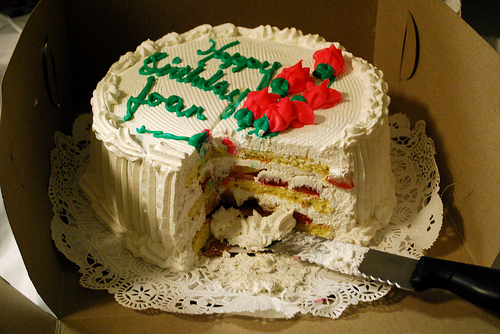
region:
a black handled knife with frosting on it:
[184, 184, 499, 319]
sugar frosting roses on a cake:
[227, 34, 357, 149]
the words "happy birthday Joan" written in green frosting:
[115, 28, 301, 168]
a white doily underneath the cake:
[27, 54, 456, 330]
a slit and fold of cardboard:
[387, 7, 435, 90]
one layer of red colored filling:
[188, 161, 360, 206]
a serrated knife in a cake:
[195, 193, 497, 318]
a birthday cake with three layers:
[65, 9, 418, 285]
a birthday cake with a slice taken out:
[75, 17, 422, 277]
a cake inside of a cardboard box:
[0, 0, 494, 330]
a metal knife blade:
[269, 217, 415, 291]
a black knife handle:
[408, 248, 498, 318]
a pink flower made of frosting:
[309, 36, 353, 71]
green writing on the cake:
[120, 35, 280, 145]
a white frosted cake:
[74, 16, 399, 277]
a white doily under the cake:
[41, 103, 448, 319]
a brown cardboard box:
[0, 0, 499, 332]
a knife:
[268, 223, 498, 316]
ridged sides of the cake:
[83, 132, 175, 251]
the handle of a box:
[388, 9, 419, 81]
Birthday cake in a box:
[0, 2, 495, 322]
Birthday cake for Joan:
[43, 9, 469, 325]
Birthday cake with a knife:
[48, 13, 497, 316]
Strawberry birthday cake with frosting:
[45, 14, 450, 330]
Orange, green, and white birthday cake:
[36, 8, 464, 328]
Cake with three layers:
[43, 1, 460, 324]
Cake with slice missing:
[40, 13, 461, 325]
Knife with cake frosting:
[212, 178, 497, 324]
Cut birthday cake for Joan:
[25, 10, 481, 322]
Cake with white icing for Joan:
[49, 20, 466, 318]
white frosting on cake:
[81, 22, 389, 259]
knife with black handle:
[312, 222, 496, 312]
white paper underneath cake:
[62, 147, 432, 308]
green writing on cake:
[115, 34, 359, 165]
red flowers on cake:
[204, 11, 371, 161]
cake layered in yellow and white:
[220, 150, 382, 255]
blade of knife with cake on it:
[255, 220, 406, 294]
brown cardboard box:
[368, 43, 476, 139]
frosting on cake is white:
[70, 22, 420, 269]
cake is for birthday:
[110, 29, 311, 161]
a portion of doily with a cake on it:
[62, 231, 140, 313]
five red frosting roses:
[250, 41, 345, 122]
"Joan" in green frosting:
[125, 71, 200, 123]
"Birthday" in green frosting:
[135, 45, 242, 105]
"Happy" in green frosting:
[195, 28, 281, 79]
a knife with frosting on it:
[235, 212, 498, 307]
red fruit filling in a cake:
[218, 163, 323, 198]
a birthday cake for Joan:
[78, 15, 413, 247]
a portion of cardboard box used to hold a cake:
[388, 14, 479, 91]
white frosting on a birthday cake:
[343, 116, 381, 153]